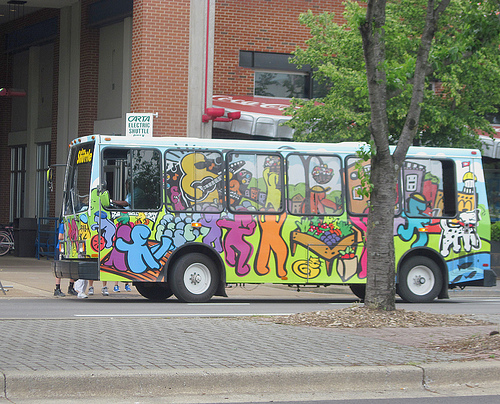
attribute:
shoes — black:
[39, 272, 87, 313]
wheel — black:
[392, 238, 475, 329]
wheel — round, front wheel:
[169, 252, 219, 310]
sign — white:
[123, 110, 153, 137]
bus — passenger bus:
[52, 132, 499, 294]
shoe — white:
[91, 281, 111, 298]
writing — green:
[126, 111, 156, 136]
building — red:
[198, 25, 245, 95]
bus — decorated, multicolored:
[38, 122, 497, 301]